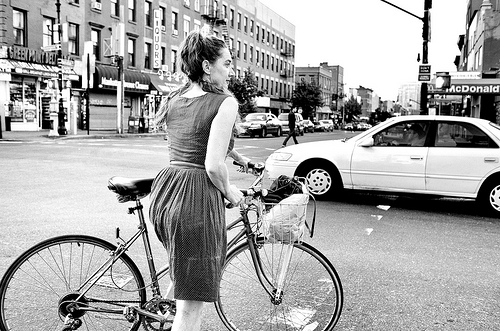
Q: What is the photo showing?
A: It is showing a street.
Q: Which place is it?
A: It is a street.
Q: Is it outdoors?
A: Yes, it is outdoors.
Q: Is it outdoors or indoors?
A: It is outdoors.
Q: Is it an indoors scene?
A: No, it is outdoors.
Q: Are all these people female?
A: No, they are both male and female.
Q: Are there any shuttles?
A: No, there are no shuttles.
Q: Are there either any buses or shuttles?
A: No, there are no shuttles or buses.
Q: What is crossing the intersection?
A: The car is crossing the intersection.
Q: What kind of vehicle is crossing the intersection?
A: The vehicle is a car.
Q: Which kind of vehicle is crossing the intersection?
A: The vehicle is a car.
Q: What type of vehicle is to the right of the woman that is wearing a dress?
A: The vehicle is a car.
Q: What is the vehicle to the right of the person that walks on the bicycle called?
A: The vehicle is a car.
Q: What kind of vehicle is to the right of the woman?
A: The vehicle is a car.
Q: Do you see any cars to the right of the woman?
A: Yes, there is a car to the right of the woman.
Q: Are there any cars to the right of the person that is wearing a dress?
A: Yes, there is a car to the right of the woman.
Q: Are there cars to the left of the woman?
A: No, the car is to the right of the woman.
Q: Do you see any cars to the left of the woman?
A: No, the car is to the right of the woman.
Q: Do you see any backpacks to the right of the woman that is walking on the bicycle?
A: No, there is a car to the right of the woman.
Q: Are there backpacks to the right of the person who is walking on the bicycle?
A: No, there is a car to the right of the woman.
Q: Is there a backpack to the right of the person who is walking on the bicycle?
A: No, there is a car to the right of the woman.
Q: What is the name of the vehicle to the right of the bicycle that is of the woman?
A: The vehicle is a car.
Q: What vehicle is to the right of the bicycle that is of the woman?
A: The vehicle is a car.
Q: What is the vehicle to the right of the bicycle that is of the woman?
A: The vehicle is a car.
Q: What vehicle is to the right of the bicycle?
A: The vehicle is a car.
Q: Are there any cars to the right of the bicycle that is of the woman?
A: Yes, there is a car to the right of the bicycle.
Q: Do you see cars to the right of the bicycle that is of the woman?
A: Yes, there is a car to the right of the bicycle.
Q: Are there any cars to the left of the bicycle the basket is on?
A: No, the car is to the right of the bicycle.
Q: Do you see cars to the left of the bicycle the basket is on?
A: No, the car is to the right of the bicycle.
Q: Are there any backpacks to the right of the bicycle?
A: No, there is a car to the right of the bicycle.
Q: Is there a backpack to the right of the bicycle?
A: No, there is a car to the right of the bicycle.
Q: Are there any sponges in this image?
A: No, there are no sponges.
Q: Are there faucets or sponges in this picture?
A: No, there are no sponges or faucets.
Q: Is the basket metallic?
A: Yes, the basket is metallic.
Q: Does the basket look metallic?
A: Yes, the basket is metallic.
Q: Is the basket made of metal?
A: Yes, the basket is made of metal.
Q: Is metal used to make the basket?
A: Yes, the basket is made of metal.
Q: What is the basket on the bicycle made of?
A: The basket is made of metal.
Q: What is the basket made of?
A: The basket is made of metal.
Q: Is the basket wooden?
A: No, the basket is metallic.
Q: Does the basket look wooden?
A: No, the basket is metallic.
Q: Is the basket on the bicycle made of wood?
A: No, the basket is made of metal.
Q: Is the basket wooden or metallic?
A: The basket is metallic.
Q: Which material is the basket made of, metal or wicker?
A: The basket is made of metal.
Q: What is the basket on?
A: The basket is on the bicycle.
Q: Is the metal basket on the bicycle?
A: Yes, the basket is on the bicycle.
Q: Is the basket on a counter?
A: No, the basket is on the bicycle.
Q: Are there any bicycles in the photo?
A: Yes, there is a bicycle.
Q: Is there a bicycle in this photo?
A: Yes, there is a bicycle.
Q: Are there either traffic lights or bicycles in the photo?
A: Yes, there is a bicycle.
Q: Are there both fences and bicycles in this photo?
A: No, there is a bicycle but no fences.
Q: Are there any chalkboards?
A: No, there are no chalkboards.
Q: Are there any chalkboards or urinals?
A: No, there are no chalkboards or urinals.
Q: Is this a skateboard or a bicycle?
A: This is a bicycle.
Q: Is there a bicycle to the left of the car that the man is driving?
A: Yes, there is a bicycle to the left of the car.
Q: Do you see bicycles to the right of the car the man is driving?
A: No, the bicycle is to the left of the car.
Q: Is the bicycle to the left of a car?
A: Yes, the bicycle is to the left of a car.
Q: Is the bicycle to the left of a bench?
A: No, the bicycle is to the left of a car.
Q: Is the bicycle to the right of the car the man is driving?
A: No, the bicycle is to the left of the car.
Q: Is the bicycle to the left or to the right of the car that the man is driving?
A: The bicycle is to the left of the car.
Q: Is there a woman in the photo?
A: Yes, there is a woman.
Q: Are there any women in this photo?
A: Yes, there is a woman.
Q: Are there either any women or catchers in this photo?
A: Yes, there is a woman.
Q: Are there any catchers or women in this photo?
A: Yes, there is a woman.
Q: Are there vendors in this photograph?
A: No, there are no vendors.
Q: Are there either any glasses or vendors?
A: No, there are no vendors or glasses.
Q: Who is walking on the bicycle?
A: The woman is walking on the bicycle.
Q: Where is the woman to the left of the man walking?
A: The woman is walking on the bicycle.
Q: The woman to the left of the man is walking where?
A: The woman is walking on the bicycle.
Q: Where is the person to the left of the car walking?
A: The woman is walking on the bicycle.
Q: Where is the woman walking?
A: The woman is walking on the bicycle.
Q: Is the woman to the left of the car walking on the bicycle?
A: Yes, the woman is walking on the bicycle.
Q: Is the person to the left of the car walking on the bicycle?
A: Yes, the woman is walking on the bicycle.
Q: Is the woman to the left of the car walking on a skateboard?
A: No, the woman is walking on the bicycle.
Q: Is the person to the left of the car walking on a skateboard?
A: No, the woman is walking on the bicycle.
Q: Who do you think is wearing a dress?
A: The woman is wearing a dress.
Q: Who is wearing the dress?
A: The woman is wearing a dress.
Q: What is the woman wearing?
A: The woman is wearing a dress.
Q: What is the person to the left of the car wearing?
A: The woman is wearing a dress.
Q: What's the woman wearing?
A: The woman is wearing a dress.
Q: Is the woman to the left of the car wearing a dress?
A: Yes, the woman is wearing a dress.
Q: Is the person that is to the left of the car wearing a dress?
A: Yes, the woman is wearing a dress.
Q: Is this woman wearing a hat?
A: No, the woman is wearing a dress.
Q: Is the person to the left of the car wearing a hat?
A: No, the woman is wearing a dress.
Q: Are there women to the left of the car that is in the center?
A: Yes, there is a woman to the left of the car.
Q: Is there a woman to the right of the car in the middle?
A: No, the woman is to the left of the car.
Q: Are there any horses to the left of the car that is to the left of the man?
A: No, there is a woman to the left of the car.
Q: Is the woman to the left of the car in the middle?
A: Yes, the woman is to the left of the car.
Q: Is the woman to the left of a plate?
A: No, the woman is to the left of the car.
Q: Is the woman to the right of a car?
A: No, the woman is to the left of a car.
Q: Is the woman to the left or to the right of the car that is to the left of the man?
A: The woman is to the left of the car.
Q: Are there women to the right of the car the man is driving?
A: No, the woman is to the left of the car.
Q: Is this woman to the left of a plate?
A: No, the woman is to the left of the car.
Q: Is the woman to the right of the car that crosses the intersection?
A: No, the woman is to the left of the car.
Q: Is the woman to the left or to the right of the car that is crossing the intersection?
A: The woman is to the left of the car.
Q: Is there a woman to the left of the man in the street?
A: Yes, there is a woman to the left of the man.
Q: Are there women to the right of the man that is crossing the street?
A: No, the woman is to the left of the man.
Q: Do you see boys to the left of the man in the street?
A: No, there is a woman to the left of the man.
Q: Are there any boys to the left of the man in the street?
A: No, there is a woman to the left of the man.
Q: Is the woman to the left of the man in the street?
A: Yes, the woman is to the left of the man.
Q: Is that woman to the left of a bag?
A: No, the woman is to the left of the man.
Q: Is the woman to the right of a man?
A: No, the woman is to the left of a man.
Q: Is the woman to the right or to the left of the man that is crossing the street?
A: The woman is to the left of the man.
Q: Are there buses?
A: No, there are no buses.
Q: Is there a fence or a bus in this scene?
A: No, there are no buses or fences.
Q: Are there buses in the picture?
A: No, there are no buses.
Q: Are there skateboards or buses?
A: No, there are no buses or skateboards.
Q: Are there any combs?
A: No, there are no combs.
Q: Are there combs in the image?
A: No, there are no combs.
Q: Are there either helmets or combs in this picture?
A: No, there are no combs or helmets.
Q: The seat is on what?
A: The seat is on the bicycle.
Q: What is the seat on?
A: The seat is on the bicycle.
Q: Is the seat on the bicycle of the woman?
A: Yes, the seat is on the bicycle.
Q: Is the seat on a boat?
A: No, the seat is on the bicycle.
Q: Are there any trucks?
A: No, there are no trucks.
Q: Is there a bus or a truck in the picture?
A: No, there are no trucks or buses.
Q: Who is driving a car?
A: The man is driving a car.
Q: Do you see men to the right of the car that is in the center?
A: Yes, there is a man to the right of the car.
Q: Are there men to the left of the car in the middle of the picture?
A: No, the man is to the right of the car.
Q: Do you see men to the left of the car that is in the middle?
A: No, the man is to the right of the car.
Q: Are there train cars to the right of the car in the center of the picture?
A: No, there is a man to the right of the car.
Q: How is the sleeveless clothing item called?
A: The clothing item is a dress.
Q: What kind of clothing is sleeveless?
A: The clothing is a dress.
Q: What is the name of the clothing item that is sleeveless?
A: The clothing item is a dress.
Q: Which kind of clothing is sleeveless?
A: The clothing is a dress.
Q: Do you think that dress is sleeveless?
A: Yes, the dress is sleeveless.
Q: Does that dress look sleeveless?
A: Yes, the dress is sleeveless.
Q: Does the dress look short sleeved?
A: No, the dress is sleeveless.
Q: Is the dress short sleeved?
A: No, the dress is sleeveless.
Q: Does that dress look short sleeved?
A: No, the dress is sleeveless.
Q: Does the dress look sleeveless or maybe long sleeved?
A: The dress is sleeveless.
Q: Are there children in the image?
A: No, there are no children.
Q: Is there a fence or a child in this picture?
A: No, there are no children or fences.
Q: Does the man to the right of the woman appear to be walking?
A: Yes, the man is walking.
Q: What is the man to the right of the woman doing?
A: The man is walking.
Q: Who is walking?
A: The man is walking.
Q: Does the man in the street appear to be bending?
A: No, the man is walking.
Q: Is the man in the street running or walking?
A: The man is walking.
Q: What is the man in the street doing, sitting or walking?
A: The man is walking.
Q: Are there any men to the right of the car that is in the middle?
A: Yes, there is a man to the right of the car.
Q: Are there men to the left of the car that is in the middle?
A: No, the man is to the right of the car.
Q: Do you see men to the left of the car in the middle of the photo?
A: No, the man is to the right of the car.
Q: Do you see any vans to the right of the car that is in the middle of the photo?
A: No, there is a man to the right of the car.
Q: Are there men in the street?
A: Yes, there is a man in the street.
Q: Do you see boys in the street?
A: No, there is a man in the street.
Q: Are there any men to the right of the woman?
A: Yes, there is a man to the right of the woman.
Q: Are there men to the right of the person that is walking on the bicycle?
A: Yes, there is a man to the right of the woman.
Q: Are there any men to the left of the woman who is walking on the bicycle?
A: No, the man is to the right of the woman.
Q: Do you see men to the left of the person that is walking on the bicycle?
A: No, the man is to the right of the woman.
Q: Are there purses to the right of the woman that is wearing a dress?
A: No, there is a man to the right of the woman.